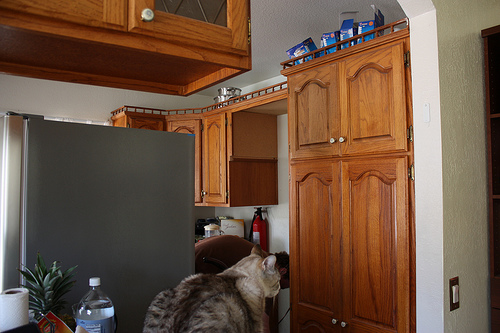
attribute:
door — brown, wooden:
[340, 41, 405, 153]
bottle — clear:
[67, 272, 121, 331]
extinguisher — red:
[251, 203, 267, 254]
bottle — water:
[72, 270, 117, 332]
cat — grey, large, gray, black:
[139, 247, 279, 332]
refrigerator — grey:
[2, 87, 226, 328]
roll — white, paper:
[3, 276, 50, 326]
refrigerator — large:
[14, 94, 210, 323]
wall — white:
[394, 29, 499, 331]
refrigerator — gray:
[9, 111, 205, 331]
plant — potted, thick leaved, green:
[21, 258, 82, 324]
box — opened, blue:
[351, 6, 378, 43]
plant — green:
[16, 253, 76, 308]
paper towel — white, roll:
[0, 285, 32, 326]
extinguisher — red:
[230, 169, 295, 279]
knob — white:
[140, 7, 155, 19]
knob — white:
[333, 136, 353, 144]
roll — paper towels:
[2, 288, 29, 330]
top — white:
[85, 275, 103, 288]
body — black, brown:
[138, 267, 257, 331]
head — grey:
[237, 239, 286, 303]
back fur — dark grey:
[161, 269, 239, 330]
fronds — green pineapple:
[10, 254, 84, 323]